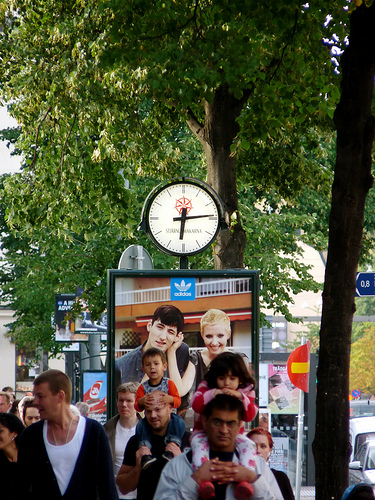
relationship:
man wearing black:
[15, 369, 119, 499] [16, 416, 122, 500]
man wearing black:
[115, 389, 188, 499] [124, 434, 187, 500]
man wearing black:
[149, 396, 287, 499] [185, 450, 236, 499]